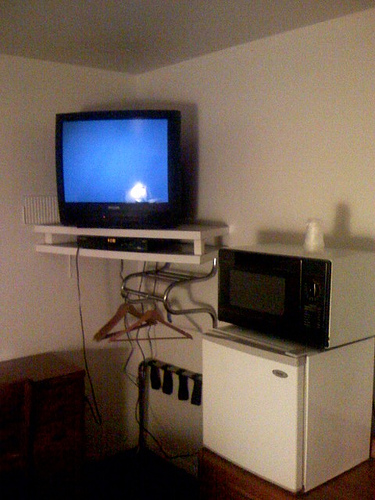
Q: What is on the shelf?
A: A television.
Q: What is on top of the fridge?
A: A microwave.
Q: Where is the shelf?
A: Attached to the wall.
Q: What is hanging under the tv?
A: Hangers.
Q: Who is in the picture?
A: No one.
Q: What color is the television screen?
A: Blue.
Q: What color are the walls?
A: White.